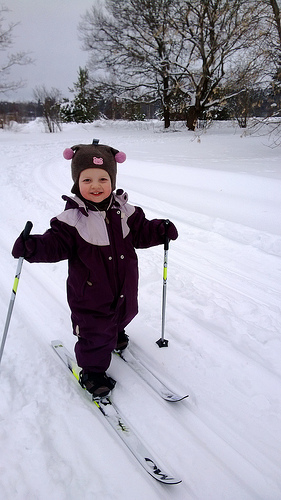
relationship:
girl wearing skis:
[11, 134, 184, 406] [48, 315, 201, 491]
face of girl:
[79, 173, 112, 200] [11, 134, 184, 406]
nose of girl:
[90, 180, 104, 193] [11, 134, 184, 406]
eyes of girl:
[81, 174, 109, 186] [11, 134, 184, 406]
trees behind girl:
[2, 2, 280, 149] [11, 134, 184, 406]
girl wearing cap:
[11, 134, 184, 406] [61, 142, 125, 191]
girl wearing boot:
[11, 134, 184, 406] [73, 363, 120, 398]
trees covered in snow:
[2, 2, 280, 149] [224, 158, 263, 367]